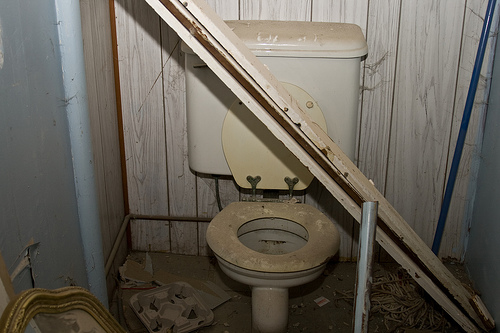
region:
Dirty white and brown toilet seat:
[205, 198, 337, 281]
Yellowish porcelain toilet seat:
[208, 80, 330, 194]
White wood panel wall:
[136, 0, 490, 245]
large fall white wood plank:
[147, 1, 491, 331]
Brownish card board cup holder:
[123, 282, 215, 332]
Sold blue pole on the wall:
[431, 0, 495, 255]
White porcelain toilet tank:
[185, 22, 368, 179]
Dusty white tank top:
[180, 18, 367, 60]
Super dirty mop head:
[350, 270, 453, 331]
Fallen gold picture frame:
[7, 286, 128, 330]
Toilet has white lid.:
[217, 96, 354, 191]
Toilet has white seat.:
[216, 198, 343, 280]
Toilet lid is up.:
[214, 150, 325, 265]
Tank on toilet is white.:
[161, 40, 368, 162]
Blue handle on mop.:
[432, 105, 482, 249]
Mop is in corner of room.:
[378, 197, 477, 330]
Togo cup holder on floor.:
[121, 271, 217, 331]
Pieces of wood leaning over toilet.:
[198, 20, 492, 322]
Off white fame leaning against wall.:
[18, 279, 113, 329]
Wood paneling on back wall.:
[383, 27, 429, 122]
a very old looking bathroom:
[3, 5, 495, 322]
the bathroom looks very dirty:
[0, 5, 498, 327]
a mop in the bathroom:
[366, 2, 494, 332]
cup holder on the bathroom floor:
[127, 280, 222, 331]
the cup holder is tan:
[126, 282, 222, 329]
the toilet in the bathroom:
[198, 93, 353, 327]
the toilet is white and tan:
[198, 73, 340, 328]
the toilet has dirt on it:
[199, 83, 343, 323]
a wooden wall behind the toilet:
[113, 2, 495, 260]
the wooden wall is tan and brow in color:
[119, 2, 487, 265]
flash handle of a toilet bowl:
[184, 60, 207, 69]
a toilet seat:
[211, 215, 260, 261]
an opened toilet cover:
[231, 127, 268, 177]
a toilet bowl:
[241, 270, 326, 288]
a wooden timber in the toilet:
[203, 40, 273, 91]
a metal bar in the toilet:
[361, 198, 391, 328]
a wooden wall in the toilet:
[391, 8, 455, 179]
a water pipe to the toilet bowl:
[118, 212, 188, 223]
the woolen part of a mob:
[379, 275, 416, 322]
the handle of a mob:
[461, 62, 479, 162]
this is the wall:
[14, 175, 49, 219]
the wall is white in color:
[8, 164, 85, 231]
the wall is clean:
[16, 163, 59, 204]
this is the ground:
[316, 303, 338, 331]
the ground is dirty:
[310, 307, 351, 332]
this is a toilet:
[183, 19, 361, 318]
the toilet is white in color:
[316, 66, 331, 78]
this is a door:
[380, 10, 440, 152]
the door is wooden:
[365, 60, 426, 115]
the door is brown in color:
[138, 38, 163, 88]